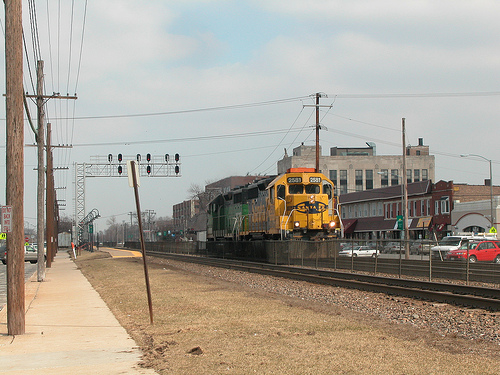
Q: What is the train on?
A: Tracks.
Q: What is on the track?
A: Train.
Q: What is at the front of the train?
A: The locomotive engine.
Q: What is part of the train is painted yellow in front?
A: A train car.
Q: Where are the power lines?
A: Lining the sidewalk.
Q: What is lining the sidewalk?
A: Utility poles.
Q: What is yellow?
A: The locomotive.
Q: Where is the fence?
A: Beside the train track.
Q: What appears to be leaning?
A: The sign.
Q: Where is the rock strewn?
A: Beside the track.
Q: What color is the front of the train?
A: Yellow.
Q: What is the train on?
A: Train tracks.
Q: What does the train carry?
A: Freight.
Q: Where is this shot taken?
A: Sidewalk.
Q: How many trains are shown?
A: 1.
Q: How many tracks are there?
A: 4.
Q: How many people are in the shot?
A: 0.